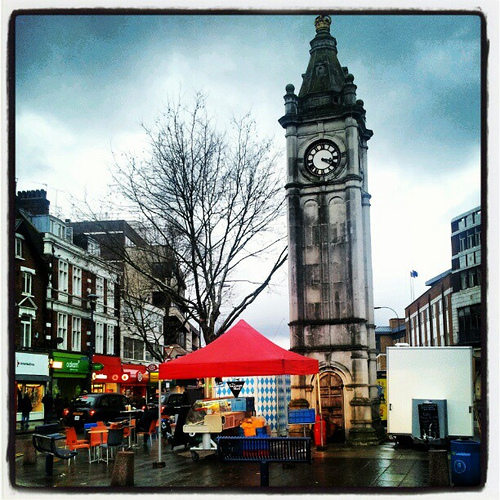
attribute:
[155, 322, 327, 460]
tent — red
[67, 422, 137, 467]
seats — orange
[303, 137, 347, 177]
clock — black, white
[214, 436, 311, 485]
bench — metallic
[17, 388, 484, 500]
pavement — wet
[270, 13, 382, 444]
tower — tall, large, gray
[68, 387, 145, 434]
car — black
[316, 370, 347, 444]
door — arched, brown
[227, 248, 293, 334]
branch — leafless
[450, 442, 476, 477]
bin — white, blue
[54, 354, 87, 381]
sign — green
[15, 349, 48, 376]
sign — white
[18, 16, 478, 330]
sky — cloudy, blue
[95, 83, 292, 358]
tree — leafless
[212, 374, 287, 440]
wall — blue, white